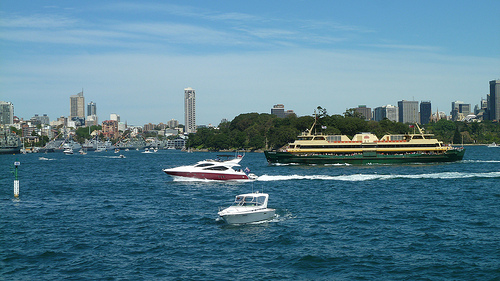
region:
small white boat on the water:
[205, 182, 294, 234]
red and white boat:
[159, 138, 262, 188]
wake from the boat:
[254, 167, 499, 181]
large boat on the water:
[261, 102, 478, 173]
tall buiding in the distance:
[178, 83, 208, 130]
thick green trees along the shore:
[187, 108, 495, 156]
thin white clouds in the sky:
[1, 1, 497, 128]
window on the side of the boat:
[204, 163, 228, 174]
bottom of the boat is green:
[262, 151, 470, 167]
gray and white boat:
[214, 187, 285, 227]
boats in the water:
[152, 155, 283, 232]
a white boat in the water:
[223, 193, 278, 231]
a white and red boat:
[158, 144, 256, 181]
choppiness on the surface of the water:
[97, 200, 177, 263]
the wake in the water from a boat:
[222, 155, 492, 189]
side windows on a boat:
[292, 141, 443, 150]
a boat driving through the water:
[153, 149, 298, 189]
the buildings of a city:
[21, 87, 201, 134]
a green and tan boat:
[271, 127, 470, 165]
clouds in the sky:
[88, 17, 253, 53]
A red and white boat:
[166, 153, 252, 180]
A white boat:
[217, 195, 278, 216]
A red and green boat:
[263, 131, 469, 162]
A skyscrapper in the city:
[183, 85, 194, 135]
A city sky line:
[348, 90, 498, 120]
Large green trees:
[200, 107, 275, 145]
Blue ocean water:
[95, 200, 182, 252]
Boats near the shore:
[48, 137, 179, 147]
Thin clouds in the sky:
[142, 14, 223, 54]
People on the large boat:
[317, 153, 362, 155]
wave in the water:
[330, 241, 351, 256]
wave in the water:
[152, 222, 189, 247]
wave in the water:
[365, 185, 395, 205]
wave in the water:
[116, 204, 150, 224]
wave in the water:
[403, 236, 442, 262]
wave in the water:
[388, 170, 418, 178]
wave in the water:
[408, 250, 439, 264]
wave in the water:
[107, 195, 126, 212]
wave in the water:
[396, 216, 423, 236]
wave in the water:
[400, 190, 429, 206]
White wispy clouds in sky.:
[169, 18, 247, 49]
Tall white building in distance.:
[179, 85, 210, 167]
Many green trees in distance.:
[236, 123, 293, 153]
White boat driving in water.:
[218, 190, 308, 249]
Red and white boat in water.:
[167, 140, 259, 192]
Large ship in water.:
[264, 115, 486, 180]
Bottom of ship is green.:
[272, 145, 489, 170]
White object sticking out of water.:
[3, 154, 50, 226]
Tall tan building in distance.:
[66, 87, 96, 129]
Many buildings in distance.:
[353, 98, 481, 124]